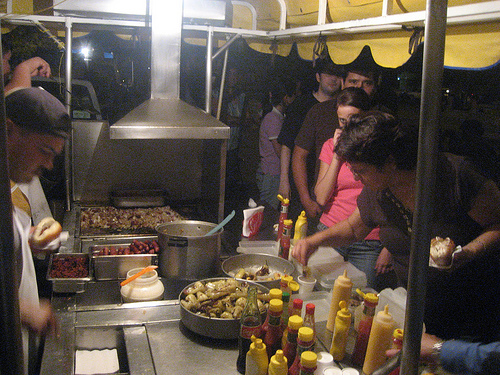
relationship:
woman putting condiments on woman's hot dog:
[300, 107, 498, 329] [428, 235, 461, 273]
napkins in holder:
[234, 191, 273, 252] [226, 192, 274, 236]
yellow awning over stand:
[185, 277, 250, 320] [2, 5, 498, 373]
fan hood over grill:
[91, 76, 248, 197] [68, 199, 204, 248]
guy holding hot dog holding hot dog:
[5, 85, 87, 370] [29, 217, 70, 256]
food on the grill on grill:
[107, 169, 176, 210] [75, 196, 195, 232]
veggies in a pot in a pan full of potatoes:
[182, 266, 270, 335] [172, 274, 273, 341]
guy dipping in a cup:
[7, 87, 119, 368] [293, 273, 316, 301]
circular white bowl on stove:
[176, 275, 304, 340] [56, 268, 233, 296]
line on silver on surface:
[68, 299, 226, 342] [41, 267, 244, 373]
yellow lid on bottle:
[260, 297, 289, 314] [267, 298, 283, 350]